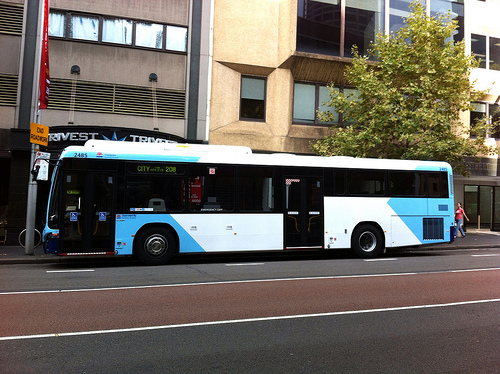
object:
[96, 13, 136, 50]
window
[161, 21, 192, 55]
window pane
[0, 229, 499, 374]
street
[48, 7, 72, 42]
window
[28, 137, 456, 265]
bus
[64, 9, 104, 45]
pane